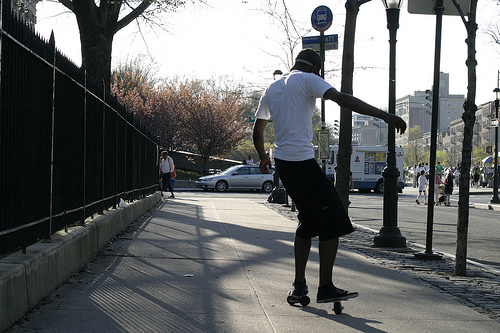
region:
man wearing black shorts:
[255, 145, 360, 243]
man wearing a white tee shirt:
[241, 73, 335, 165]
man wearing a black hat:
[290, 43, 328, 68]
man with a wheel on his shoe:
[329, 293, 347, 318]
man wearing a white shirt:
[159, 157, 174, 178]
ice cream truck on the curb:
[318, 135, 406, 195]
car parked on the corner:
[196, 152, 271, 194]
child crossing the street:
[413, 158, 432, 200]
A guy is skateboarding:
[248, 42, 408, 319]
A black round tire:
[210, 171, 231, 196]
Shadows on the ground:
[11, 190, 493, 330]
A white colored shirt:
[250, 65, 337, 165]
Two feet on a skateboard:
[280, 275, 360, 317]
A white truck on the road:
[316, 137, 407, 197]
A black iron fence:
[0, 0, 165, 260]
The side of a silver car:
[195, 156, 280, 196]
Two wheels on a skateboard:
[280, 287, 315, 307]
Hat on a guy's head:
[288, 42, 326, 80]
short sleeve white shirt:
[253, 72, 326, 163]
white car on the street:
[204, 158, 277, 189]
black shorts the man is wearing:
[275, 152, 355, 232]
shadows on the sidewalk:
[127, 177, 394, 332]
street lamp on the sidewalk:
[373, 1, 410, 248]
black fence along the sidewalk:
[2, 3, 159, 253]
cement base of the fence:
[2, 184, 165, 321]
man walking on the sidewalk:
[158, 148, 176, 193]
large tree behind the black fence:
[70, 0, 137, 91]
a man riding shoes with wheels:
[238, 45, 393, 330]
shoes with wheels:
[275, 266, 365, 317]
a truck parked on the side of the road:
[317, 138, 418, 205]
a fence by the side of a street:
[4, 27, 191, 317]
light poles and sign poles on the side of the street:
[329, 5, 490, 280]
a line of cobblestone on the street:
[367, 240, 497, 315]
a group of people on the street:
[411, 155, 471, 205]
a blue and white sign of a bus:
[299, 1, 347, 33]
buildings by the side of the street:
[328, 59, 494, 184]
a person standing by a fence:
[145, 143, 181, 203]